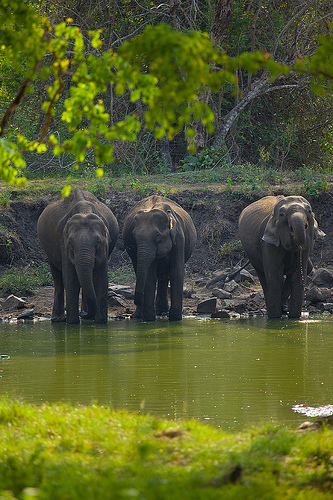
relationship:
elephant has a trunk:
[121, 191, 197, 321] [136, 242, 153, 317]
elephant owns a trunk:
[121, 191, 197, 321] [136, 242, 153, 317]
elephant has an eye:
[121, 191, 197, 321] [155, 231, 165, 239]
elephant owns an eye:
[121, 191, 197, 321] [155, 231, 165, 239]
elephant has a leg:
[121, 191, 197, 321] [266, 266, 284, 318]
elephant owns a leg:
[121, 191, 197, 321] [266, 266, 284, 318]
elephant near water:
[121, 191, 197, 321] [3, 315, 332, 431]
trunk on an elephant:
[136, 242, 153, 317] [121, 191, 197, 321]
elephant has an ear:
[121, 191, 197, 321] [158, 210, 173, 253]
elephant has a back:
[121, 191, 197, 321] [248, 195, 283, 210]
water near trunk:
[3, 315, 332, 431] [136, 242, 153, 317]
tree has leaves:
[2, 3, 150, 195] [114, 81, 126, 96]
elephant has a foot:
[121, 191, 197, 321] [52, 311, 66, 322]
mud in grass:
[162, 431, 180, 443] [2, 395, 332, 499]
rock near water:
[198, 296, 224, 317] [3, 315, 332, 431]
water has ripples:
[3, 315, 332, 431] [294, 400, 333, 422]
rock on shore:
[198, 296, 224, 317] [1, 252, 332, 324]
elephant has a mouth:
[121, 191, 197, 321] [288, 245, 300, 253]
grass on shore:
[2, 395, 332, 499] [1, 252, 332, 324]